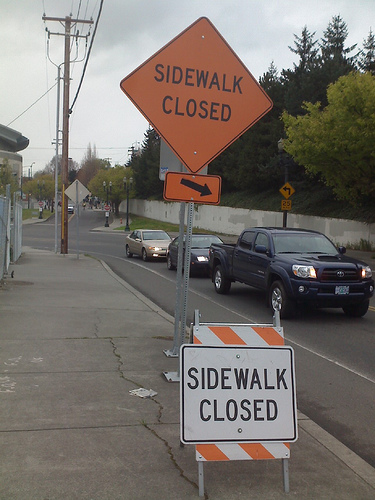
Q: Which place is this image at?
A: It is at the road.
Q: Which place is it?
A: It is a road.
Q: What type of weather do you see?
A: It is cloudy.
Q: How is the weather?
A: It is cloudy.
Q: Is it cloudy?
A: Yes, it is cloudy.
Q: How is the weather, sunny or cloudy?
A: It is cloudy.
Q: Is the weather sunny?
A: No, it is cloudy.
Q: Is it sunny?
A: No, it is cloudy.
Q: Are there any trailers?
A: No, there are no trailers.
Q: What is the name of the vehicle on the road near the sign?
A: The vehicle is a car.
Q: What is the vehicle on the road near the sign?
A: The vehicle is a car.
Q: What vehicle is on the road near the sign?
A: The vehicle is a car.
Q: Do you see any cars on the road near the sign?
A: Yes, there is a car on the road.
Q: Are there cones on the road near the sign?
A: No, there is a car on the road.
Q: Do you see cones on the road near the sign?
A: No, there is a car on the road.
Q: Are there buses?
A: No, there are no buses.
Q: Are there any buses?
A: No, there are no buses.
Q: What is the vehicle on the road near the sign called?
A: The vehicle is a car.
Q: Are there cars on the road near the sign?
A: Yes, there is a car on the road.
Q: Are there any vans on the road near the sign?
A: No, there is a car on the road.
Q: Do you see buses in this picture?
A: No, there are no buses.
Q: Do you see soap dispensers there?
A: No, there are no soap dispensers.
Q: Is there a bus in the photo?
A: No, there are no buses.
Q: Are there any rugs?
A: No, there are no rugs.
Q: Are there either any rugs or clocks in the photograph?
A: No, there are no rugs or clocks.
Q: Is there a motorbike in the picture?
A: No, there are no motorcycles.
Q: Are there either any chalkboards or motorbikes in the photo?
A: No, there are no motorbikes or chalkboards.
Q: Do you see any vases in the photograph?
A: No, there are no vases.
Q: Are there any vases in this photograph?
A: No, there are no vases.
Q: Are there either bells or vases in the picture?
A: No, there are no vases or bells.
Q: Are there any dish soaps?
A: No, there are no dish soaps.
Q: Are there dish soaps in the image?
A: No, there are no dish soaps.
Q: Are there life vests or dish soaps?
A: No, there are no dish soaps or life vests.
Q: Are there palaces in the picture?
A: No, there are no palaces.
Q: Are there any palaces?
A: No, there are no palaces.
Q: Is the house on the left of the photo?
A: Yes, the house is on the left of the image.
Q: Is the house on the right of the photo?
A: No, the house is on the left of the image.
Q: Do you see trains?
A: No, there are no trains.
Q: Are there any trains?
A: No, there are no trains.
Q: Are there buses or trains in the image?
A: No, there are no trains or buses.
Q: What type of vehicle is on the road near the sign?
A: The vehicle is a car.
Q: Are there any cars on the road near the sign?
A: Yes, there is a car on the road.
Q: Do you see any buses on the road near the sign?
A: No, there is a car on the road.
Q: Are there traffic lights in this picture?
A: No, there are no traffic lights.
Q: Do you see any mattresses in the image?
A: No, there are no mattresses.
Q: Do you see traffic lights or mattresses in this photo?
A: No, there are no mattresses or traffic lights.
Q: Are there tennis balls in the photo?
A: No, there are no tennis balls.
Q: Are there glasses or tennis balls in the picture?
A: No, there are no tennis balls or glasses.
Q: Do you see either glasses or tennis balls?
A: No, there are no tennis balls or glasses.